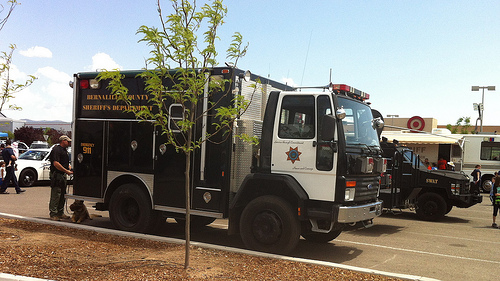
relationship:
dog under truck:
[70, 199, 91, 223] [69, 68, 382, 256]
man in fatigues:
[50, 135, 74, 221] [47, 142, 67, 214]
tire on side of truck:
[238, 192, 300, 255] [64, 67, 384, 255]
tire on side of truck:
[413, 187, 448, 219] [380, 136, 482, 220]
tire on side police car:
[18, 167, 39, 190] [0, 148, 71, 187]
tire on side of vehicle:
[173, 212, 215, 224] [73, 72, 380, 253]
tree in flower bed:
[95, 0, 261, 274] [2, 209, 449, 279]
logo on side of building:
[400, 107, 435, 146] [376, 107, 445, 171]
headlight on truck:
[330, 179, 360, 207] [61, 42, 399, 252]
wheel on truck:
[238, 192, 302, 256] [61, 42, 399, 252]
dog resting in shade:
[70, 199, 91, 223] [63, 209, 112, 223]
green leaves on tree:
[103, 1, 265, 147] [101, 2, 273, 279]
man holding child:
[0, 134, 22, 195] [7, 145, 19, 166]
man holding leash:
[49, 134, 71, 217] [64, 174, 68, 216]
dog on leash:
[70, 199, 91, 223] [64, 174, 68, 216]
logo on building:
[407, 116, 425, 133] [383, 112, 436, 148]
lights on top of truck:
[319, 80, 404, 112] [84, 49, 452, 264]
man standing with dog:
[50, 135, 74, 221] [63, 200, 93, 230]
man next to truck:
[50, 135, 74, 221] [61, 42, 399, 252]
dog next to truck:
[63, 200, 93, 230] [61, 42, 399, 252]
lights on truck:
[345, 179, 356, 202] [69, 68, 382, 256]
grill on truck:
[356, 175, 378, 202] [69, 68, 382, 256]